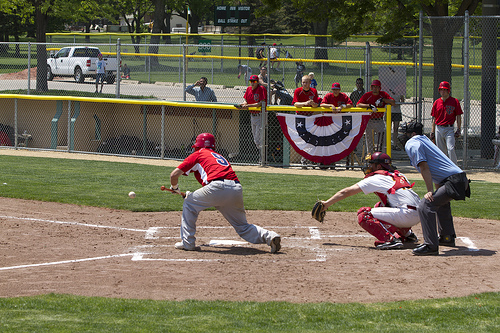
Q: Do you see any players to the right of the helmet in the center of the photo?
A: Yes, there is a player to the right of the helmet.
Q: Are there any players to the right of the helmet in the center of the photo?
A: Yes, there is a player to the right of the helmet.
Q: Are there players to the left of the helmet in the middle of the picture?
A: No, the player is to the right of the helmet.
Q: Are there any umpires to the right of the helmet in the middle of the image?
A: No, there is a player to the right of the helmet.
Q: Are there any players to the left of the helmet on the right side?
A: Yes, there is a player to the left of the helmet.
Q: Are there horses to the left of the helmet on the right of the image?
A: No, there is a player to the left of the helmet.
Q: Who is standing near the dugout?
A: The player is standing near the dugout.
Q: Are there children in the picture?
A: No, there are no children.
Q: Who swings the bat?
A: The batter swings the bat.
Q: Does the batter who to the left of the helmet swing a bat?
A: Yes, the batter swings a bat.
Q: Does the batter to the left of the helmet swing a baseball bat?
A: No, the batter swings a bat.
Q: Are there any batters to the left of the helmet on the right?
A: Yes, there is a batter to the left of the helmet.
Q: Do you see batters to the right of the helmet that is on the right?
A: No, the batter is to the left of the helmet.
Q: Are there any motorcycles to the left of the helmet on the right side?
A: No, there is a batter to the left of the helmet.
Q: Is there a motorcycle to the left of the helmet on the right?
A: No, there is a batter to the left of the helmet.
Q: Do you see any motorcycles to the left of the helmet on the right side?
A: No, there is a batter to the left of the helmet.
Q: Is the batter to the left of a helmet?
A: Yes, the batter is to the left of a helmet.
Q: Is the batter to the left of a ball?
A: No, the batter is to the left of a helmet.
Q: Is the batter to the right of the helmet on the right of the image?
A: No, the batter is to the left of the helmet.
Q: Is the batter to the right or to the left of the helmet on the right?
A: The batter is to the left of the helmet.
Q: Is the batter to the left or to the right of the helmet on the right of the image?
A: The batter is to the left of the helmet.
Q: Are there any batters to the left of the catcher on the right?
A: Yes, there is a batter to the left of the catcher.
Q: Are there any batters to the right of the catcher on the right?
A: No, the batter is to the left of the catcher.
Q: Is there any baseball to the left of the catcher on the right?
A: No, there is a batter to the left of the catcher.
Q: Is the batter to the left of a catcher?
A: Yes, the batter is to the left of a catcher.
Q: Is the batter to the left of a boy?
A: No, the batter is to the left of a catcher.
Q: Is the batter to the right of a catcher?
A: No, the batter is to the left of a catcher.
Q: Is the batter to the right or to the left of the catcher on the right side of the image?
A: The batter is to the left of the catcher.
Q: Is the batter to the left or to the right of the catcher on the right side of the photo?
A: The batter is to the left of the catcher.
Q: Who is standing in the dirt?
A: The batter is standing in the dirt.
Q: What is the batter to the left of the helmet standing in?
A: The batter is standing in the dirt.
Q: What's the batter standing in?
A: The batter is standing in the dirt.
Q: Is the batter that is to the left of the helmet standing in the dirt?
A: Yes, the batter is standing in the dirt.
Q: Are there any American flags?
A: No, there are no American flags.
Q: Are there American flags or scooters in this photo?
A: No, there are no American flags or scooters.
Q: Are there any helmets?
A: Yes, there is a helmet.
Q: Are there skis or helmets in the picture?
A: Yes, there is a helmet.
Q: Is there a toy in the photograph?
A: No, there are no toys.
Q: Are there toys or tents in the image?
A: No, there are no toys or tents.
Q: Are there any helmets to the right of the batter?
A: Yes, there is a helmet to the right of the batter.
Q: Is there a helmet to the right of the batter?
A: Yes, there is a helmet to the right of the batter.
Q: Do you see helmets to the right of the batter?
A: Yes, there is a helmet to the right of the batter.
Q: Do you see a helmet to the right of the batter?
A: Yes, there is a helmet to the right of the batter.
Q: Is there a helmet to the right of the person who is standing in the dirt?
A: Yes, there is a helmet to the right of the batter.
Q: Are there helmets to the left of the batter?
A: No, the helmet is to the right of the batter.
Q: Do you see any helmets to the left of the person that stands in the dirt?
A: No, the helmet is to the right of the batter.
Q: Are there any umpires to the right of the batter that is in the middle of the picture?
A: No, there is a helmet to the right of the batter.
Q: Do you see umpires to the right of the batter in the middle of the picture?
A: No, there is a helmet to the right of the batter.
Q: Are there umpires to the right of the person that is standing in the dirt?
A: No, there is a helmet to the right of the batter.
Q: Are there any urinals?
A: No, there are no urinals.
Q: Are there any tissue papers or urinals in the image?
A: No, there are no urinals or tissue papers.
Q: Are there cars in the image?
A: No, there are no cars.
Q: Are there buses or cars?
A: No, there are no cars or buses.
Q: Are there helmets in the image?
A: Yes, there is a helmet.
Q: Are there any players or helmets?
A: Yes, there is a helmet.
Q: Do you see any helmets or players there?
A: Yes, there is a helmet.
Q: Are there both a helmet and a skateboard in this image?
A: No, there is a helmet but no skateboards.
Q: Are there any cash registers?
A: No, there are no cash registers.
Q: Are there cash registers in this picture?
A: No, there are no cash registers.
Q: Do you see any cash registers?
A: No, there are no cash registers.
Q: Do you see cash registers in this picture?
A: No, there are no cash registers.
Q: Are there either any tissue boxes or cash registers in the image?
A: No, there are no cash registers or tissue boxes.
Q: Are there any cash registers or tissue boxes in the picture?
A: No, there are no cash registers or tissue boxes.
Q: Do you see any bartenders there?
A: No, there are no bartenders.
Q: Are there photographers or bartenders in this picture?
A: No, there are no bartenders or photographers.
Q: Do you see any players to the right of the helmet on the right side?
A: Yes, there is a player to the right of the helmet.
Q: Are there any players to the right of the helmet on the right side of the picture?
A: Yes, there is a player to the right of the helmet.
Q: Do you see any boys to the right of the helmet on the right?
A: No, there is a player to the right of the helmet.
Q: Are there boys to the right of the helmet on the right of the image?
A: No, there is a player to the right of the helmet.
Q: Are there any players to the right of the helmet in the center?
A: Yes, there is a player to the right of the helmet.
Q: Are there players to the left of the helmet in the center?
A: No, the player is to the right of the helmet.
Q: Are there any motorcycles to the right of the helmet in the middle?
A: No, there is a player to the right of the helmet.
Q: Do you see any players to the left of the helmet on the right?
A: Yes, there is a player to the left of the helmet.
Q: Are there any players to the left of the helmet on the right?
A: Yes, there is a player to the left of the helmet.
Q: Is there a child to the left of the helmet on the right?
A: No, there is a player to the left of the helmet.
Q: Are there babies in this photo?
A: No, there are no babies.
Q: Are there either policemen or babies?
A: No, there are no babies or policemen.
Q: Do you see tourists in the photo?
A: No, there are no tourists.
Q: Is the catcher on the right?
A: Yes, the catcher is on the right of the image.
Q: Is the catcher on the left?
A: No, the catcher is on the right of the image.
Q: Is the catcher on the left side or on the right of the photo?
A: The catcher is on the right of the image.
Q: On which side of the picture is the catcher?
A: The catcher is on the right of the image.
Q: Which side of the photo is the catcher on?
A: The catcher is on the right of the image.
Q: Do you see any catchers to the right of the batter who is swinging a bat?
A: Yes, there is a catcher to the right of the batter.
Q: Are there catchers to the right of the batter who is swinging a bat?
A: Yes, there is a catcher to the right of the batter.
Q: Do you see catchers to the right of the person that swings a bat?
A: Yes, there is a catcher to the right of the batter.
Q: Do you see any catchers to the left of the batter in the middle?
A: No, the catcher is to the right of the batter.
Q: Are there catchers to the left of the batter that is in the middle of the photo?
A: No, the catcher is to the right of the batter.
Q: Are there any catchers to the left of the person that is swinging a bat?
A: No, the catcher is to the right of the batter.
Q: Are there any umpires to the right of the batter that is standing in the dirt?
A: No, there is a catcher to the right of the batter.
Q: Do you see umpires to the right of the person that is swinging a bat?
A: No, there is a catcher to the right of the batter.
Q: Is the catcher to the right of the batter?
A: Yes, the catcher is to the right of the batter.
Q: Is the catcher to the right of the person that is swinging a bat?
A: Yes, the catcher is to the right of the batter.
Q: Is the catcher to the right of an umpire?
A: No, the catcher is to the right of the batter.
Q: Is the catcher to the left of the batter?
A: No, the catcher is to the right of the batter.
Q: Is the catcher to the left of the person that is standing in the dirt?
A: No, the catcher is to the right of the batter.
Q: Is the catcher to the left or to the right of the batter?
A: The catcher is to the right of the batter.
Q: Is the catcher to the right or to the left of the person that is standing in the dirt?
A: The catcher is to the right of the batter.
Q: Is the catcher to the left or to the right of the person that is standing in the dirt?
A: The catcher is to the right of the batter.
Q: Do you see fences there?
A: Yes, there is a fence.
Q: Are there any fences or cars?
A: Yes, there is a fence.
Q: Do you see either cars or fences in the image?
A: Yes, there is a fence.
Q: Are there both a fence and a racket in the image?
A: No, there is a fence but no rackets.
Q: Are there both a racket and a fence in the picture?
A: No, there is a fence but no rackets.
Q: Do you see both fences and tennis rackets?
A: No, there is a fence but no rackets.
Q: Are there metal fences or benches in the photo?
A: Yes, there is a metal fence.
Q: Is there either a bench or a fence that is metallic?
A: Yes, the fence is metallic.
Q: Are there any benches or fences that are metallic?
A: Yes, the fence is metallic.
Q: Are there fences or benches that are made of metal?
A: Yes, the fence is made of metal.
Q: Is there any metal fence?
A: Yes, there is a fence that is made of metal.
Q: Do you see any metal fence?
A: Yes, there is a fence that is made of metal.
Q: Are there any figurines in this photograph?
A: No, there are no figurines.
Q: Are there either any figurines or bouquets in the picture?
A: No, there are no figurines or bouquets.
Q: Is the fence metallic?
A: Yes, the fence is metallic.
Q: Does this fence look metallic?
A: Yes, the fence is metallic.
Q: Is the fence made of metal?
A: Yes, the fence is made of metal.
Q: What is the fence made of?
A: The fence is made of metal.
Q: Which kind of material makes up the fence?
A: The fence is made of metal.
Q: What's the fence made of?
A: The fence is made of metal.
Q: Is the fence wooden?
A: No, the fence is metallic.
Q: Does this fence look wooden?
A: No, the fence is metallic.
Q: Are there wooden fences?
A: No, there is a fence but it is metallic.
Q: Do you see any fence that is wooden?
A: No, there is a fence but it is metallic.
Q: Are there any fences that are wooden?
A: No, there is a fence but it is metallic.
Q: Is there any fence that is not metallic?
A: No, there is a fence but it is metallic.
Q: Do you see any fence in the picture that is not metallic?
A: No, there is a fence but it is metallic.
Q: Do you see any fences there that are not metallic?
A: No, there is a fence but it is metallic.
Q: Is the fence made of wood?
A: No, the fence is made of metal.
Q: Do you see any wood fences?
A: No, there is a fence but it is made of metal.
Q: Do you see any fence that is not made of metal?
A: No, there is a fence but it is made of metal.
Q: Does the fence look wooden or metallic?
A: The fence is metallic.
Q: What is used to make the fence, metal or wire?
A: The fence is made of metal.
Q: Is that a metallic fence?
A: Yes, that is a metallic fence.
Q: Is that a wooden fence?
A: No, that is a metallic fence.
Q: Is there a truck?
A: Yes, there is a truck.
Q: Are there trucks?
A: Yes, there is a truck.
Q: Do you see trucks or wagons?
A: Yes, there is a truck.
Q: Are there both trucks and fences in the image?
A: Yes, there are both a truck and a fence.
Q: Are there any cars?
A: No, there are no cars.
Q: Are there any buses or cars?
A: No, there are no cars or buses.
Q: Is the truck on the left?
A: Yes, the truck is on the left of the image.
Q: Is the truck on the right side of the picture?
A: No, the truck is on the left of the image.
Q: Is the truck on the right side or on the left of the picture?
A: The truck is on the left of the image.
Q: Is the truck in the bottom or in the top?
A: The truck is in the top of the image.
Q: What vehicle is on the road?
A: The vehicle is a truck.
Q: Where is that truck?
A: The truck is on the road.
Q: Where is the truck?
A: The truck is on the road.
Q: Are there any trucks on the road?
A: Yes, there is a truck on the road.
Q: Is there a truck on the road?
A: Yes, there is a truck on the road.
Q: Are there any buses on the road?
A: No, there is a truck on the road.